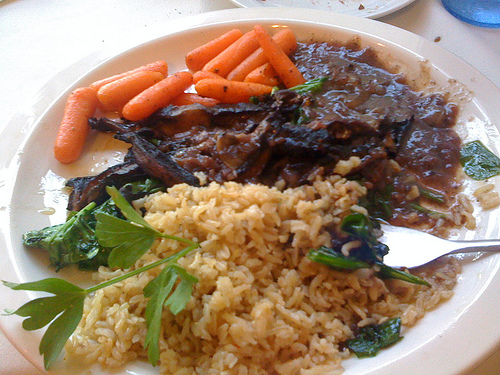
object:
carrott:
[54, 87, 96, 163]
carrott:
[89, 60, 167, 113]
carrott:
[96, 71, 164, 112]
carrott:
[122, 71, 193, 120]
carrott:
[185, 34, 243, 72]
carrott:
[202, 30, 260, 78]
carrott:
[245, 63, 282, 86]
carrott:
[254, 24, 306, 89]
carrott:
[195, 79, 273, 103]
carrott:
[193, 71, 226, 85]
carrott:
[172, 93, 220, 107]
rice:
[147, 181, 333, 312]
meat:
[132, 133, 200, 188]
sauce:
[291, 34, 467, 197]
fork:
[378, 226, 500, 270]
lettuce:
[22, 202, 109, 272]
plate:
[4, 88, 51, 276]